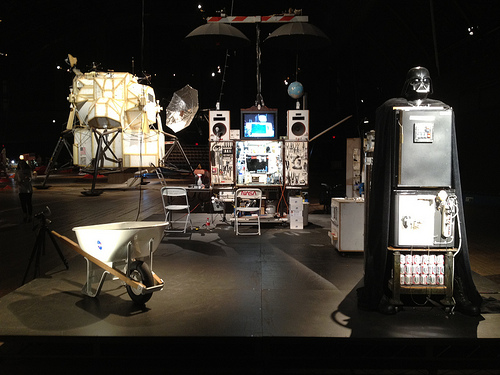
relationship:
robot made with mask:
[344, 60, 474, 320] [403, 62, 435, 100]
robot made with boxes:
[344, 60, 474, 320] [391, 105, 457, 295]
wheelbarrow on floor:
[50, 218, 171, 312] [6, 181, 499, 334]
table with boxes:
[160, 183, 317, 234] [203, 104, 312, 187]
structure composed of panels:
[68, 60, 168, 172] [70, 75, 167, 167]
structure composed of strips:
[68, 60, 168, 172] [74, 75, 166, 164]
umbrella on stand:
[162, 77, 215, 134] [150, 134, 206, 178]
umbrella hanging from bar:
[181, 25, 244, 48] [203, 13, 309, 24]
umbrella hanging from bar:
[265, 24, 330, 45] [203, 13, 309, 24]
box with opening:
[233, 143, 287, 185] [246, 156, 269, 172]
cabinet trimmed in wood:
[326, 198, 364, 253] [335, 200, 345, 257]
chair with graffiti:
[231, 189, 264, 236] [236, 189, 264, 200]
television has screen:
[239, 105, 280, 141] [243, 115, 275, 134]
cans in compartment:
[400, 252, 444, 285] [388, 244, 459, 295]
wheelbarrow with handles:
[50, 218, 171, 312] [48, 229, 165, 293]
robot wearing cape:
[344, 60, 474, 320] [355, 96, 499, 315]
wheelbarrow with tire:
[50, 218, 171, 312] [123, 257, 156, 305]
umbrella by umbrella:
[181, 25, 244, 48] [265, 24, 330, 45]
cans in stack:
[400, 252, 444, 285] [400, 253, 445, 287]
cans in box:
[400, 252, 444, 285] [388, 244, 459, 295]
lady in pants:
[14, 159, 35, 224] [19, 189, 35, 220]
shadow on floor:
[15, 278, 185, 330] [6, 181, 499, 334]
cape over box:
[355, 96, 499, 315] [394, 108, 453, 188]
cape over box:
[355, 96, 499, 315] [392, 185, 458, 244]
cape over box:
[355, 96, 499, 315] [395, 248, 449, 286]